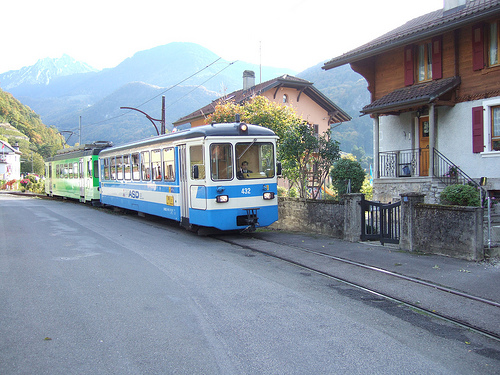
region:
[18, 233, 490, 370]
train tracks on the side of the road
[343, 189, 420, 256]
black color gate at the entrance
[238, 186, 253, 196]
white numbers on blue color background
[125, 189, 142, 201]
blue color text is painted on white background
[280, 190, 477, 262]
the wall with its faded paint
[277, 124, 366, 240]
trees with green leaves behind the fence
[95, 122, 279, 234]
A blue train car.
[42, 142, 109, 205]
Green train car.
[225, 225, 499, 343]
Silver tracks in front of a train.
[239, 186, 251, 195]
White 432 on the front of a blue train.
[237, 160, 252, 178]
Man with black hair driving a train.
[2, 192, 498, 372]
A grey paved road.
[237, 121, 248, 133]
Round illuminated train light.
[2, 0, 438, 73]
A white sky.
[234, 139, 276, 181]
Larger front train window.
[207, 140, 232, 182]
Smaller front train window.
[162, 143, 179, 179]
Window of a bus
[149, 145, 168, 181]
Window of a bus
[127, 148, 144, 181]
Window of a bus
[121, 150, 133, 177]
Window of a bus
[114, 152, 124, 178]
Window of a bus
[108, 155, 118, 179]
Window of a bus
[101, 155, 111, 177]
Window of a bus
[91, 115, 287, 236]
a bus parked on side street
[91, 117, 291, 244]
the bus is white and blue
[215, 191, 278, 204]
white headlights of bus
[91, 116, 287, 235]
roof of bus is black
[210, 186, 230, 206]
light on a train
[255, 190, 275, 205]
light on a train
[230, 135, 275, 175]
window on a train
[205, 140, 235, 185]
window on a train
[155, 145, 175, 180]
window on a train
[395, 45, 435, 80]
window on a building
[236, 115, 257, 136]
light on a train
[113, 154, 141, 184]
windows on a train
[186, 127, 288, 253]
blue and white train on track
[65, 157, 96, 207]
green and white train on track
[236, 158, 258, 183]
conductor of train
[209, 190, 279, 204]
lights on front of train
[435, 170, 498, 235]
steps leading to house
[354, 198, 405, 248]
black gate into yard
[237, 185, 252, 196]
numbers on front of train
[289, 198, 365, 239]
wall around yard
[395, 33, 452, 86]
window on two story house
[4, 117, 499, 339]
the trains on the track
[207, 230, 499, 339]
the track is made of metal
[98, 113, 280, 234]
the train is blue and white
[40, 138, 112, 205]
the train is green and white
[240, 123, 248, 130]
the light is white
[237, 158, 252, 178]
the person is sitting